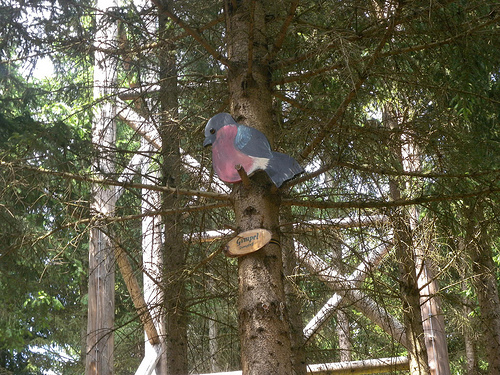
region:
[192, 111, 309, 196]
Bluebird in tree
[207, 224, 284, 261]
Wooden sign in tree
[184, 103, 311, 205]
Wooden bird on perch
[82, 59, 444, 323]
Wooden scaffold in forest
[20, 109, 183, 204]
Pine tree branches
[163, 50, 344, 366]
Pine tree in forest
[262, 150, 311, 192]
Wooden bird has a blue tail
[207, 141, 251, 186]
Wooden bird has a red belly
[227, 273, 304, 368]
Pine tree bark is rough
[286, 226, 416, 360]
Wooden logs form a cross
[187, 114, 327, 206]
red black and white bird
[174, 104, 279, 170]
red black and white bird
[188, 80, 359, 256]
red black and white bird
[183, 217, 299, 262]
a sign on a tree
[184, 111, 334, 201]
a wooden bird nailed to a tree trunk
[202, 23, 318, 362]
the trunk of a large pine tree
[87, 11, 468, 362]
a large wooden framework in the background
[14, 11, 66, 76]
a patch of sunny sky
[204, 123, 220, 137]
the eye of a painted bird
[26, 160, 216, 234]
a dead branch sticking off a pine tree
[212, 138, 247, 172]
a painted bird's red belly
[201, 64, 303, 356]
a pine tree with two pieces of wood nailed to it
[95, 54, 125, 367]
a tall beam supporting a structure's corner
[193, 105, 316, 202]
bird with red chest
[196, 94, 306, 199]
blue, pink and white bird on brown tree branch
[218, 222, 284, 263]
tan and green sign attached to brown tree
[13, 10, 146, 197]
brown tree with green leaves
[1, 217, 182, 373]
brown tree with green leaves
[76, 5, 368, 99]
brown tree with green leaves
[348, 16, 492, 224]
brown tree with green leaves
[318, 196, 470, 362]
brown tree with green leaves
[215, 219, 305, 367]
brown tree with tan sign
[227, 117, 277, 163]
blue wing of bird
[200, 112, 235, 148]
blue head of bird